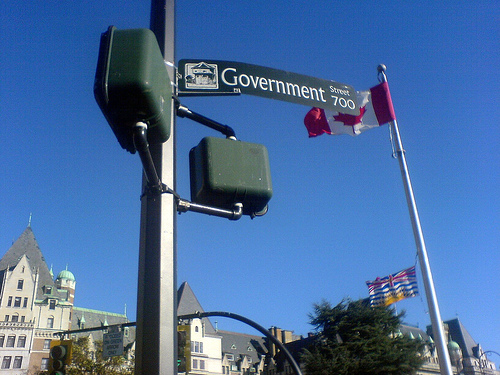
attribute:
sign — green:
[183, 57, 350, 108]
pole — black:
[130, 221, 186, 302]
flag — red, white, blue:
[370, 263, 429, 303]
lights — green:
[43, 341, 72, 372]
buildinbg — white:
[4, 259, 51, 368]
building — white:
[4, 245, 54, 373]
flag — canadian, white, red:
[300, 103, 403, 130]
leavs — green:
[331, 315, 354, 345]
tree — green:
[337, 329, 356, 344]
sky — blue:
[10, 36, 43, 59]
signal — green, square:
[98, 29, 175, 142]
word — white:
[224, 66, 327, 103]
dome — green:
[451, 336, 461, 354]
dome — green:
[51, 265, 77, 278]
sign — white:
[99, 329, 130, 362]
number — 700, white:
[329, 95, 358, 114]